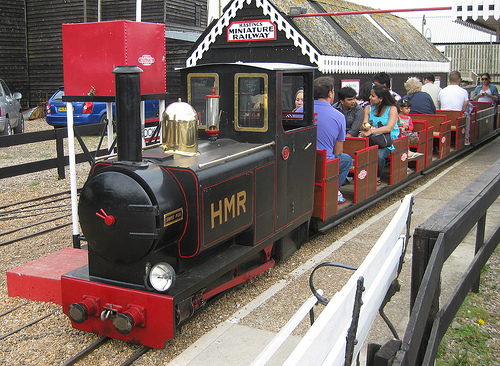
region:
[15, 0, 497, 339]
Black and red attraction, shaped like train ride.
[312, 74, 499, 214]
People on train cars.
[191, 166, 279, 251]
"HMR," written on train's side.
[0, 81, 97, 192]
Cars parked in gravel.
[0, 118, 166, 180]
Fence, separating cars from train track.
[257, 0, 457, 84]
Sloped roof with white detailing.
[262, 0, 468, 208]
Roof shades passengers on train.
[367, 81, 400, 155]
Brunette woman with turquoise outfit.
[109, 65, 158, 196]
Black smokestack on front of train.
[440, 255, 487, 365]
Patchy grass near outer fence.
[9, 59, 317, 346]
Train Engine Black Red Gold letters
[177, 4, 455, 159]
Building Minature Railway Station White Trim Brown building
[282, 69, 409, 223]
Train cars People Family Purple shirt Blue shirt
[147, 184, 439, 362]
Bench white metal arms next to train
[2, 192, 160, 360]
Train tracks Stones Red Platform Train engine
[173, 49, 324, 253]
Train engine three windows black Gold trim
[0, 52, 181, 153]
Cars Blue suv Gray car Red box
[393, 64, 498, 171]
People Train Car Red Trim Brown seats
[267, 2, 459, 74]
Brown roof white trim moss on roof train station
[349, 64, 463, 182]
Girl Train car pink shirt pony tail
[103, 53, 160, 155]
Black train stack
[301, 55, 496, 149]
People on a train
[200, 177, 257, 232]
Gold words saying HMR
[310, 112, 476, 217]
Red train seats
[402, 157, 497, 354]
Black fence along train track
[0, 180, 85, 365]
Black train tracks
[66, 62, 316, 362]
Black and red train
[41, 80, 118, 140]
A blue car that is parked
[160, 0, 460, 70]
The roof of the train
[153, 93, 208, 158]
Gold train bell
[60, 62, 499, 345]
miniature train filled with passengers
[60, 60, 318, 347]
black miniature train engine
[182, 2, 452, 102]
miniature train railway station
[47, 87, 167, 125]
parked blue compact car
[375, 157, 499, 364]
black wooden fence along track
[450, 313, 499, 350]
yellow dandelion in grass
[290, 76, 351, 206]
man in blue collared shirt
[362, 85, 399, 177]
woman in green sleeveless shirt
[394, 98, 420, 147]
small child in red shirt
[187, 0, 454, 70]
white lattice along roof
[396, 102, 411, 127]
a small child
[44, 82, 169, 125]
a blue car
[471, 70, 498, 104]
a woman in sunglasses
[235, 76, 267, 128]
a window on a train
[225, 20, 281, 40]
a sign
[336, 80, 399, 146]
a man and woman talking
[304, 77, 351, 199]
a man in a blue shirt and jeans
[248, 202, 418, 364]
a white bench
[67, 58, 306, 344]
a train engine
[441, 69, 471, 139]
a man in a white shirt